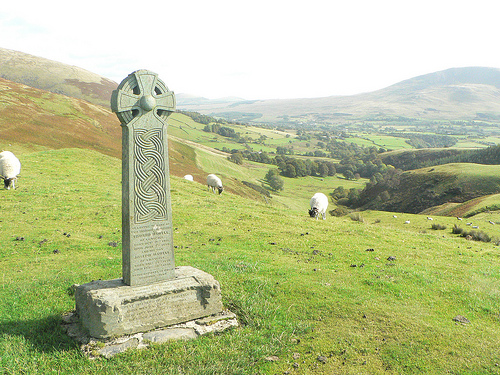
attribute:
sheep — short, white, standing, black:
[4, 147, 338, 234]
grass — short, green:
[9, 100, 500, 370]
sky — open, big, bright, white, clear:
[3, 0, 499, 97]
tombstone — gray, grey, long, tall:
[63, 72, 259, 347]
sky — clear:
[155, 0, 435, 54]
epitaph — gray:
[215, 219, 371, 277]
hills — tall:
[320, 49, 499, 139]